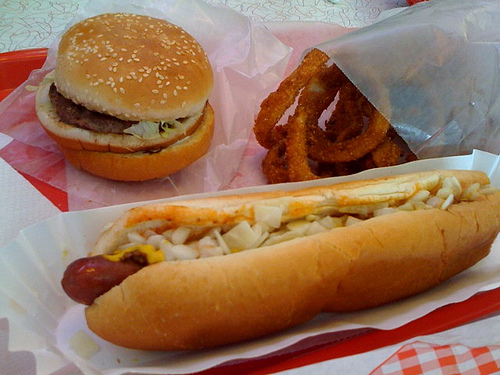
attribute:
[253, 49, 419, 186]
onion rings — brown, crispy, fried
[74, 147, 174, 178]
roll — hot dog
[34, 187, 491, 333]
hotdog — footlong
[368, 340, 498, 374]
paper — red, white, checked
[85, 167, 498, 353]
bun — HOT DOG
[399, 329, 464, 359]
tablecloth — red, white, checked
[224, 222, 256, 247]
onion — chopped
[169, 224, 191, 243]
onion — chopped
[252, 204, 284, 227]
onion — chopped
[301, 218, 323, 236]
onion — chopped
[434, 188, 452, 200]
onion — chopped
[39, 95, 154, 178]
patty — HAMBURGER 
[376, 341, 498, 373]
table cloth — checkered, red and white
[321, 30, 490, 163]
bag — clear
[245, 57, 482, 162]
rings — PACK , ONION  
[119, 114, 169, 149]
lettuce — green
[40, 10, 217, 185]
sandwich — toasted, triple-decker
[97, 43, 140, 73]
seeds — sesame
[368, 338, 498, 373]
checkered cloth — red, checked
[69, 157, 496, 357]
hotdog — grilled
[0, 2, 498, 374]
tray — red, plastic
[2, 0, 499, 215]
wrapper — paper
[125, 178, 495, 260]
onions — chopped, white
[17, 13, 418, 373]
tray — red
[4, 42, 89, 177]
tray — red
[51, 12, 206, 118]
bun — sesame seed